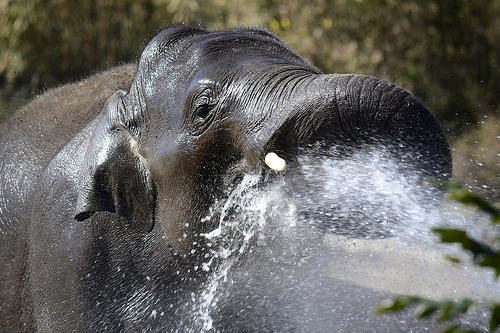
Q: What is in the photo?
A: An elephant.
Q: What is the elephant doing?
A: Standing.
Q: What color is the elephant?
A: Grey.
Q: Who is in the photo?
A: No one.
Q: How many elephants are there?
A: 1.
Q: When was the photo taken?
A: Day time.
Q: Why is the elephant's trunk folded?
A: Water is splashing on it.